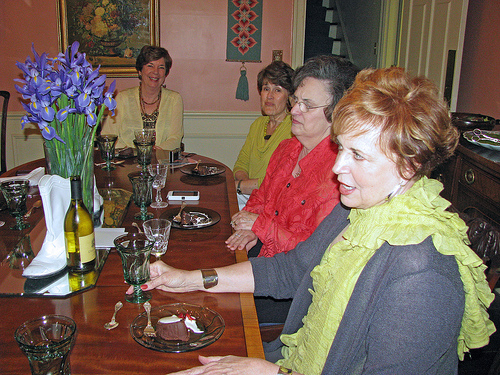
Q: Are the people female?
A: Yes, all the people are female.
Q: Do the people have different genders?
A: No, all the people are female.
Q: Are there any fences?
A: No, there are no fences.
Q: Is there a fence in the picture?
A: No, there are no fences.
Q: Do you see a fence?
A: No, there are no fences.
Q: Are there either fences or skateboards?
A: No, there are no fences or skateboards.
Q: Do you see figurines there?
A: No, there are no figurines.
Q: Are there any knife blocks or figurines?
A: No, there are no figurines or knife blocks.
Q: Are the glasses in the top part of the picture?
A: Yes, the glasses are in the top of the image.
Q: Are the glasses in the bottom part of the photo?
A: No, the glasses are in the top of the image.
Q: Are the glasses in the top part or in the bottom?
A: The glasses are in the top of the image.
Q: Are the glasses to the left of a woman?
A: No, the glasses are to the right of a woman.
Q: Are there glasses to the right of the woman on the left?
A: Yes, there are glasses to the right of the woman.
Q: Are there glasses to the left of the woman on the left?
A: No, the glasses are to the right of the woman.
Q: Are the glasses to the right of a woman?
A: Yes, the glasses are to the right of a woman.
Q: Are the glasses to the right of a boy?
A: No, the glasses are to the right of a woman.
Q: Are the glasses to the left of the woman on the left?
A: No, the glasses are to the right of the woman.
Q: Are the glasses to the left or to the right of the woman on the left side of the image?
A: The glasses are to the right of the woman.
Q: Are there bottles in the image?
A: Yes, there is a bottle.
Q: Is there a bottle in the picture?
A: Yes, there is a bottle.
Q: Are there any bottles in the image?
A: Yes, there is a bottle.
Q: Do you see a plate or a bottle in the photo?
A: Yes, there is a bottle.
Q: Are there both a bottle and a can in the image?
A: No, there is a bottle but no cans.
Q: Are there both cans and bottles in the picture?
A: No, there is a bottle but no cans.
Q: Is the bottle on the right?
A: No, the bottle is on the left of the image.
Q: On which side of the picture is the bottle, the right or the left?
A: The bottle is on the left of the image.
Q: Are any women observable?
A: Yes, there is a woman.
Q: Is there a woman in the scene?
A: Yes, there is a woman.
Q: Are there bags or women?
A: Yes, there is a woman.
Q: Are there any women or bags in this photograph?
A: Yes, there is a woman.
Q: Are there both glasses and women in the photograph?
A: Yes, there are both a woman and glasses.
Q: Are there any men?
A: No, there are no men.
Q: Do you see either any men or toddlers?
A: No, there are no men or toddlers.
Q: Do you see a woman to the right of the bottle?
A: Yes, there is a woman to the right of the bottle.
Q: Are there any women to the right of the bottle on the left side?
A: Yes, there is a woman to the right of the bottle.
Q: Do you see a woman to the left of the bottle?
A: No, the woman is to the right of the bottle.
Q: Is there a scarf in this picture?
A: Yes, there is a scarf.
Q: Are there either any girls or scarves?
A: Yes, there is a scarf.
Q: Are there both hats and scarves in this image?
A: No, there is a scarf but no hats.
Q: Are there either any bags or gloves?
A: No, there are no bags or gloves.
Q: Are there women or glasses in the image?
A: Yes, there is a woman.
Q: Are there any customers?
A: No, there are no customers.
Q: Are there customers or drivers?
A: No, there are no customers or drivers.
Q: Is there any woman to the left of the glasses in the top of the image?
A: Yes, there is a woman to the left of the glasses.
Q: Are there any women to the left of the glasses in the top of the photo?
A: Yes, there is a woman to the left of the glasses.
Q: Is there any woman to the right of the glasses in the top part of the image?
A: No, the woman is to the left of the glasses.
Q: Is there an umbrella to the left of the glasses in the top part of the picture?
A: No, there is a woman to the left of the glasses.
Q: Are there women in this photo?
A: Yes, there is a woman.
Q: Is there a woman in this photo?
A: Yes, there is a woman.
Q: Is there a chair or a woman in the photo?
A: Yes, there is a woman.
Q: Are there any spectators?
A: No, there are no spectators.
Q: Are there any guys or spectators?
A: No, there are no spectators or guys.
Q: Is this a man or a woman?
A: This is a woman.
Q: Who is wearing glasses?
A: The woman is wearing glasses.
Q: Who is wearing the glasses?
A: The woman is wearing glasses.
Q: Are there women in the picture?
A: Yes, there is a woman.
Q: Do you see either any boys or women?
A: Yes, there is a woman.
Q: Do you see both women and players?
A: No, there is a woman but no players.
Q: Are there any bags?
A: No, there are no bags.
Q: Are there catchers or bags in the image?
A: No, there are no bags or catchers.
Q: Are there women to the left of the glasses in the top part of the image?
A: Yes, there is a woman to the left of the glasses.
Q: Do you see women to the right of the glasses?
A: No, the woman is to the left of the glasses.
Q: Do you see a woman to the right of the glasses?
A: No, the woman is to the left of the glasses.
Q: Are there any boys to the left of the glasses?
A: No, there is a woman to the left of the glasses.